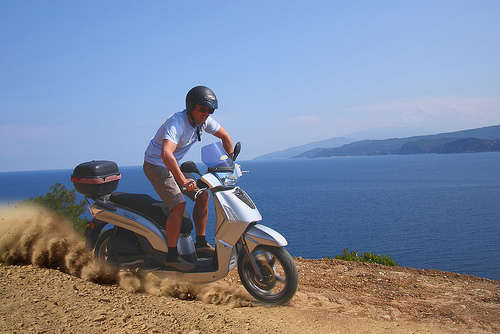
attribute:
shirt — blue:
[145, 114, 213, 164]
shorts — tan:
[138, 162, 194, 208]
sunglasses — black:
[200, 106, 215, 114]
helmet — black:
[185, 83, 219, 110]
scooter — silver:
[62, 134, 313, 313]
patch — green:
[353, 245, 384, 263]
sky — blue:
[0, 1, 499, 124]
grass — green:
[333, 247, 398, 264]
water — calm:
[88, 80, 465, 278]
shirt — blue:
[168, 119, 190, 158]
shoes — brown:
[162, 242, 227, 272]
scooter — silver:
[41, 146, 313, 305]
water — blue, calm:
[0, 150, 500, 280]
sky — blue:
[4, 3, 499, 169]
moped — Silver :
[69, 141, 298, 306]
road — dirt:
[4, 197, 498, 332]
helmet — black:
[185, 86, 220, 131]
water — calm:
[277, 157, 494, 249]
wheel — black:
[233, 237, 305, 309]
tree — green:
[18, 187, 95, 253]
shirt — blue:
[141, 106, 223, 168]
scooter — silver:
[70, 141, 299, 304]